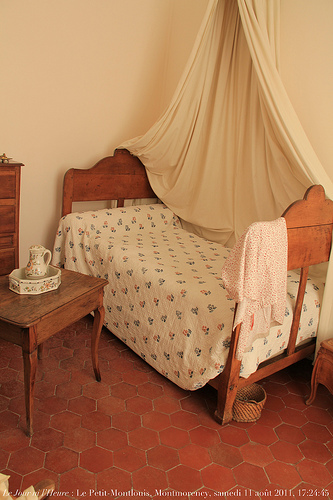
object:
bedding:
[52, 206, 323, 392]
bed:
[50, 149, 330, 425]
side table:
[303, 337, 332, 404]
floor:
[0, 418, 331, 497]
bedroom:
[0, 0, 332, 497]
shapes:
[143, 448, 182, 469]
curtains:
[120, 1, 332, 246]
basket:
[233, 383, 267, 421]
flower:
[182, 329, 187, 335]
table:
[0, 270, 106, 437]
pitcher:
[25, 244, 50, 279]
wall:
[0, 1, 330, 274]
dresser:
[0, 163, 22, 266]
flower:
[145, 281, 152, 288]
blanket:
[222, 220, 289, 359]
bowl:
[6, 267, 60, 294]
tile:
[166, 464, 204, 492]